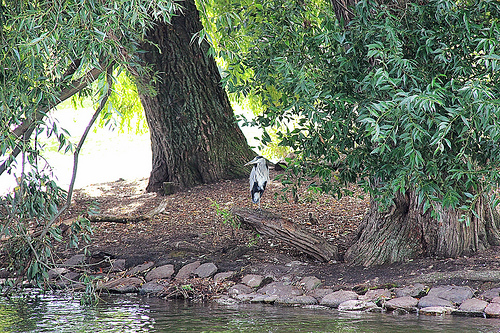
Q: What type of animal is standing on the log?
A: A bird.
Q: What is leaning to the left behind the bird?
A: A tree.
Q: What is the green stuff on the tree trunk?
A: Moss.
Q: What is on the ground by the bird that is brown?
A: Leaves.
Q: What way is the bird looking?
A: To his right.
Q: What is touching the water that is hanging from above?
A: Tree branches.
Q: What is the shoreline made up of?
A: Rocks and dirt.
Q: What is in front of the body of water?
A: Rocks.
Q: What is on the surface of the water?
A: Ripples.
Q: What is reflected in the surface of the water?
A: Light.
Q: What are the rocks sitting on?
A: Dirt ground.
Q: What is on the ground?
A: Leaves and straw.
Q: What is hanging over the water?
A: Green leafy tree branches.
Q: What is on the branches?
A: Leaves.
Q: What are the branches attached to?
A: Tree trunk.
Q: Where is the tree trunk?
A: In the ground on dirt hill.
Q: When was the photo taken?
A: Daytime.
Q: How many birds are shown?
A: One.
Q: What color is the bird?
A: Black and white.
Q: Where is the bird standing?
A: Tree branch.